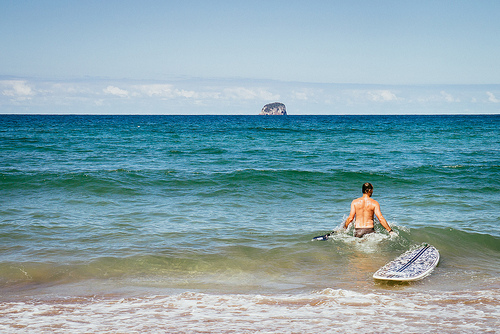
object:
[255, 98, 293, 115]
rock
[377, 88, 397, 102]
clouds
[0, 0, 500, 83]
sky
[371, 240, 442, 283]
board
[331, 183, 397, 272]
man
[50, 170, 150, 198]
waves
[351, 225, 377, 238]
trunks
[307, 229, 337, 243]
object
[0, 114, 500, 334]
water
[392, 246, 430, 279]
stripes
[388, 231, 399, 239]
hand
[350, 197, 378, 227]
back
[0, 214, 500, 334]
island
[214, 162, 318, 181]
wave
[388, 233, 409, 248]
foam